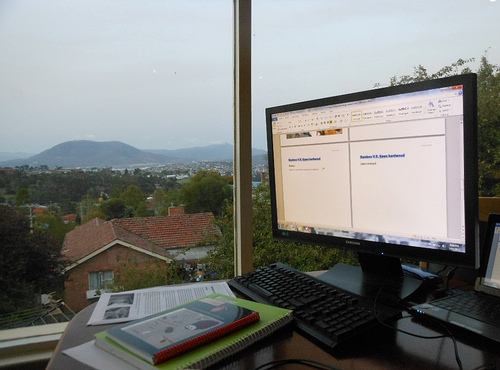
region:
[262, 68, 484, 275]
A FLAT SCREENED COMPUTER MONITOR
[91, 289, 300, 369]
A GREEN NOTEBOOK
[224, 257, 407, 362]
A BLACK COMPUTER KEYBOARD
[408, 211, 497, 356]
AN OPENED LAPTOP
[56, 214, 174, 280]
A ROOF ON A HOUSE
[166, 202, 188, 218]
A ROOFTOP CHIMNEY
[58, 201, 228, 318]
TWO HOUSES IN THE BACKGROUND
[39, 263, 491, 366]
A BROWN WOODEN DESK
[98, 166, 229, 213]
TREES IN THE DISTANCE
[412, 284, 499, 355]
A LAPTOP KEYBOARD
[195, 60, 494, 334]
a black computer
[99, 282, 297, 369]
a green notebook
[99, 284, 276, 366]
a small notebook with a red binder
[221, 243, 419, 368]
a black keyboard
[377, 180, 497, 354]
a black laptop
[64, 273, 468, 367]
a brown wooden desk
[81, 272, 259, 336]
a white piece of paper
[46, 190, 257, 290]
a brown building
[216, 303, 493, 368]
black wires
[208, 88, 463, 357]
a black computer with a black keyboard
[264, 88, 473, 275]
computer monitor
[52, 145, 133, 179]
mountain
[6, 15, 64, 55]
white clouds against blue sky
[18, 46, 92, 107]
white clouds against blue sky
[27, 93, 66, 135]
white clouds against blue sky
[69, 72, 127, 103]
white clouds against blue sky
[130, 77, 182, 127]
white clouds against blue sky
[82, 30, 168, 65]
white clouds against blue sky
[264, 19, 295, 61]
white clouds against blue sky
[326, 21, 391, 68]
white clouds against blue sky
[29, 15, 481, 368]
A computer sitting on a desk.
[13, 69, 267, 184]
Mountains in the background.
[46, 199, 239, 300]
House with a red roof.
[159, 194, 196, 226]
Chimney on rooftop.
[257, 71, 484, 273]
Computer monitor turned on.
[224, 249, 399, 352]
A black keyboard.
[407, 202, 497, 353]
Part of a laptop.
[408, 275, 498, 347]
Part of laptop keyboard.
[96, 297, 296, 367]
A sprial bound notebook.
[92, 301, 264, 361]
Book with a red binding.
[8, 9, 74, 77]
white clouds in blue sky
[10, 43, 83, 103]
white clouds in blue sky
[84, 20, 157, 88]
white clouds in blue sky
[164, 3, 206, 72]
white clouds in blue sky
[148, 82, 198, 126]
white clouds in blue sky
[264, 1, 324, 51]
white clouds in blue sky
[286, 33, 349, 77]
white clouds in blue sky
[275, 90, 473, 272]
monitor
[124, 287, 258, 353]
red and black book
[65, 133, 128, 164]
purple mountain